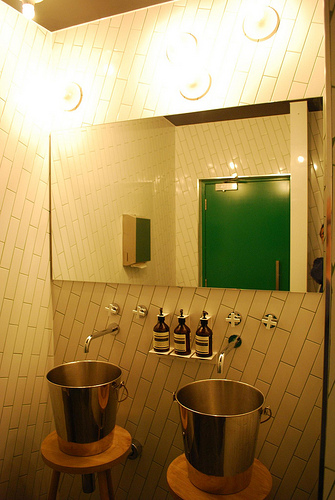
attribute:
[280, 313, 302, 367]
tile — white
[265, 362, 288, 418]
tile — white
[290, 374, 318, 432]
tile — white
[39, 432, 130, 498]
stool — wooden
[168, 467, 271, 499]
stool — wooden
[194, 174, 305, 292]
door — green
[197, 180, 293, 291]
door — Green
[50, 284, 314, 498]
tile — White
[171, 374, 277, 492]
bucket — silver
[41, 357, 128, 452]
bucket — silver